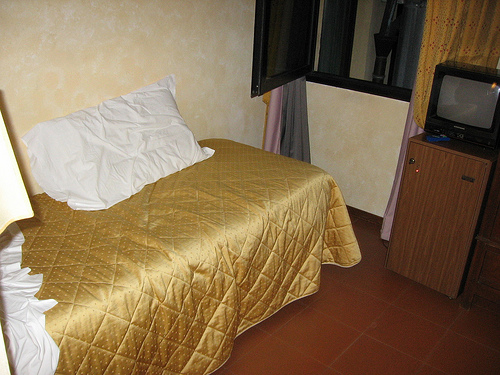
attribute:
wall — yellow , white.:
[0, 6, 301, 161]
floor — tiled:
[283, 275, 407, 330]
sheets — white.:
[1, 223, 63, 374]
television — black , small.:
[410, 57, 497, 127]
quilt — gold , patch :
[29, 192, 363, 354]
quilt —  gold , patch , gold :
[20, 128, 372, 373]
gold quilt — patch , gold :
[87, 237, 297, 326]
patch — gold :
[178, 237, 205, 257]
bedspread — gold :
[8, 133, 370, 373]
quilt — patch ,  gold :
[167, 192, 250, 230]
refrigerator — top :
[382, 124, 498, 301]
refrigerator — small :
[375, 120, 498, 311]